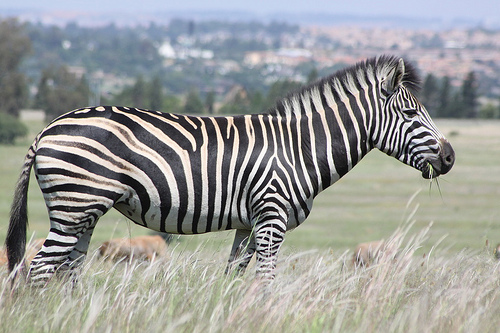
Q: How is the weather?
A: Sunny.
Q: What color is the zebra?
A: Black and white.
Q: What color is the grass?
A: Green.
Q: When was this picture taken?
A: Daytime.